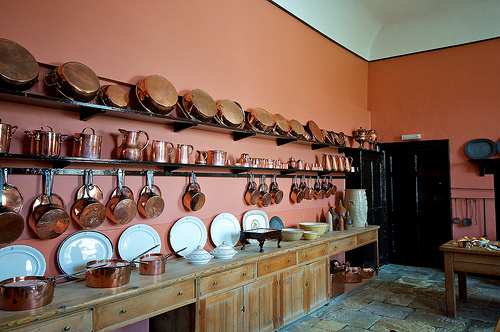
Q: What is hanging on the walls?
A: Pots.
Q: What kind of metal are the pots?
A: They are copper.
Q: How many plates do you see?
A: 6 plates.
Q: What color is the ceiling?
A: It's white.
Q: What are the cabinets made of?
A: They are made of wood.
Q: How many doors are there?
A: 2 doors.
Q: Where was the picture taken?
A: In a restaurant kitchen.